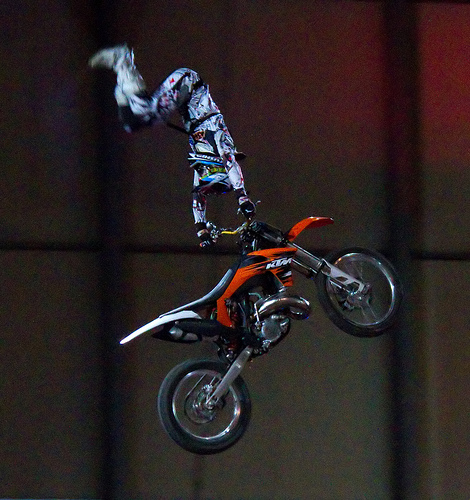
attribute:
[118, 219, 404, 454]
motorbike — orange, black, white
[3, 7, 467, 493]
air — grey, dark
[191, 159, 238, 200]
helmet — blue, black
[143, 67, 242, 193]
uniform — black, white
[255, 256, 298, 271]
logo — white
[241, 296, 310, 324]
exhaust pipe — chrome, curved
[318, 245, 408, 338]
front wheel — large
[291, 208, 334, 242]
front fender — orange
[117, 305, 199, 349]
tail — white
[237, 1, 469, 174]
background patch — red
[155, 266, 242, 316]
seat — black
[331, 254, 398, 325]
spokes — silver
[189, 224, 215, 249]
glove — black, silver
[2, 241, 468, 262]
large line — black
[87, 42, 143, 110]
boots — white